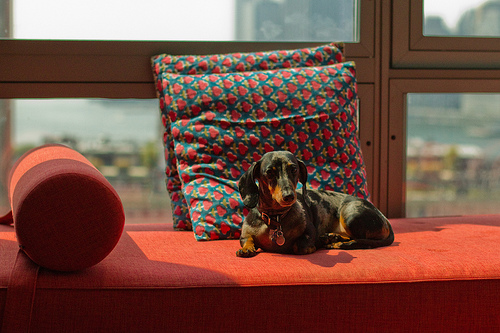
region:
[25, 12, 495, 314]
a dog on a couch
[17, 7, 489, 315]
the couch is a burnt orange color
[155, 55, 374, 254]
there is a blue and red flower designed pillow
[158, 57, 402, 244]
the dog looks small next to the pillows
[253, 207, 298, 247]
he has on a dog collar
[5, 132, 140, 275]
this is a circular pillow on the couch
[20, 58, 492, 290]
this couch has a unique design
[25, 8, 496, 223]
the dog is in some type of high rise apartment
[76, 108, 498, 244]
the image of the city in the background is blurry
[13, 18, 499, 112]
window frames on the window area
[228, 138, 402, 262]
little dachshund on a day bed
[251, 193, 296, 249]
little dachshund is wearing a collar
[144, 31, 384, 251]
little dachshund is dwarfed by the large throw pillows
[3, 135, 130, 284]
lumbar roll and pillow both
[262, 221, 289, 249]
little dachshund is wearing tags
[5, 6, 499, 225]
view of the world outside through the window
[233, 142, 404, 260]
little dachshund is a two-tone brown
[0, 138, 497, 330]
day bed is red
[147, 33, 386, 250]
the red of the throw pillows matches the bed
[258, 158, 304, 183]
little dachshund has dark gentle eyes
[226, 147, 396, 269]
a dog on a couch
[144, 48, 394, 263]
a dog leaning against the pillows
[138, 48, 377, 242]
pillows on the couch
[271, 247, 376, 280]
the shadow of the dog on the couch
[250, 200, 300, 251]
the dog's collar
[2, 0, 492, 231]
windows behind the couch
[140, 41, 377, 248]
the pillows on the couch have a pattern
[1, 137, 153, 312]
an armrest on the couch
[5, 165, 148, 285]
shadow from the arrmrest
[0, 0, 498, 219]
the weather outside is overcast